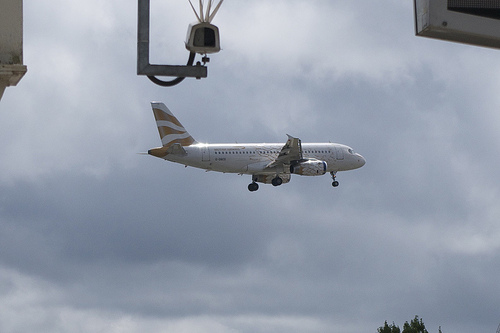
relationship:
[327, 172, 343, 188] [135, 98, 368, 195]
landing gear of airplane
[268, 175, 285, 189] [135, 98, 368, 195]
landing gear of airplane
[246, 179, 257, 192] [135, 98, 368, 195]
landing gear of airplane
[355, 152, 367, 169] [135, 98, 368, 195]
nose of airplane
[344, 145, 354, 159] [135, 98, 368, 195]
cockpit of airplane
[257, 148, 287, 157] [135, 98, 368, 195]
window of airplane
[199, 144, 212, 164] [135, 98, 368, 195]
door of airplane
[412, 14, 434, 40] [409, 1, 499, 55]
corner of sign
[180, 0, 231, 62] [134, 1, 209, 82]
equipment on bracket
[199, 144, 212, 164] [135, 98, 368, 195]
door on airplane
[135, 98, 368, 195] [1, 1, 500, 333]
airplane in sky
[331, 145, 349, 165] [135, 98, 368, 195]
door of airplane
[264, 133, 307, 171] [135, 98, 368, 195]
wing of airplane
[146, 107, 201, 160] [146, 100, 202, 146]
marking on tail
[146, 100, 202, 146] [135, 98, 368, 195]
tail of airplane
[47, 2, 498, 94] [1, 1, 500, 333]
clouds in sky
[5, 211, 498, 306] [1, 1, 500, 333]
clouds in sky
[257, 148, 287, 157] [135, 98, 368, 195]
window on airplane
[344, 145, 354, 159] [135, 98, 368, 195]
cockpit on airplane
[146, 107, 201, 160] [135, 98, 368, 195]
marking on airplane